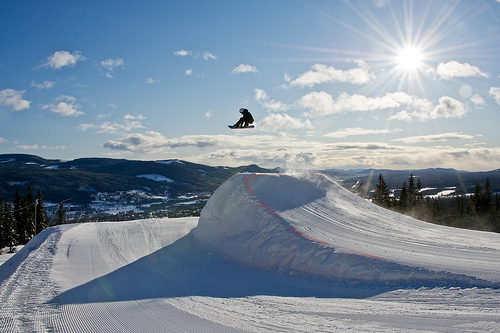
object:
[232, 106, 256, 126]
person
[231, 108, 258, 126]
tricks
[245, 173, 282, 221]
line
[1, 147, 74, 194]
snow hill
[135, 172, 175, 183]
snow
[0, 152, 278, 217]
mountains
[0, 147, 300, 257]
background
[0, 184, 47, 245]
trees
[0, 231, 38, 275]
side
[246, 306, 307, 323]
prints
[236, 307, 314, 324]
tires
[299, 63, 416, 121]
clouds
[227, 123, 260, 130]
snowboard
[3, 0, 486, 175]
day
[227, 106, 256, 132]
snowboarder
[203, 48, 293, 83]
air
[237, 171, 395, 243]
slope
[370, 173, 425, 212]
pine trees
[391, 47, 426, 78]
sun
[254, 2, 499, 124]
sky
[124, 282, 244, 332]
ground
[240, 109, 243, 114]
helmet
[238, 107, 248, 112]
head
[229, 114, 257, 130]
riding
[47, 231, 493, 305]
shadow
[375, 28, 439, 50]
rays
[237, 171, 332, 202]
ramp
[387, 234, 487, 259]
surface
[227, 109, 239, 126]
front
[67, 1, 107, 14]
part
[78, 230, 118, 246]
part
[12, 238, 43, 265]
edge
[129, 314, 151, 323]
part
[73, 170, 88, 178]
part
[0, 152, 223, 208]
hills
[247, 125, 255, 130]
part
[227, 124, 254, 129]
board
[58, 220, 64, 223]
part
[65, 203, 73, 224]
post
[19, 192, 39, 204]
part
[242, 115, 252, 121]
part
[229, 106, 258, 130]
jumper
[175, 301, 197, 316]
patches